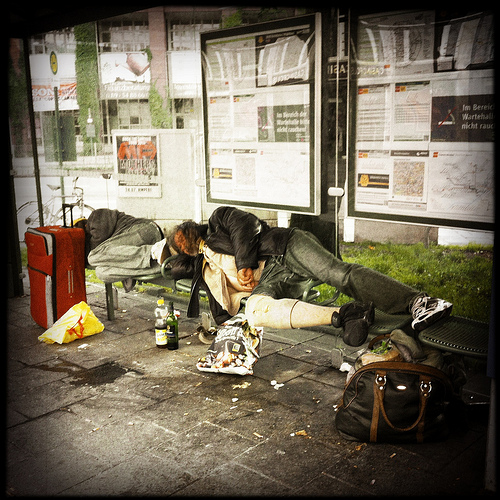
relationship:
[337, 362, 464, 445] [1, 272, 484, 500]
bag on sidewalk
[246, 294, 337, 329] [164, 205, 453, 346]
prostetic on vagabond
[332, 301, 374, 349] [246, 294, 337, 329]
shoe on prostetic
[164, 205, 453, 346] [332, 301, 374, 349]
vagabond wearing a shoe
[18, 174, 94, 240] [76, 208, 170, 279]
bike behind hobo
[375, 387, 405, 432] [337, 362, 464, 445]
handle on bag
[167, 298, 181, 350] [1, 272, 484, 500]
bottle on sidewalk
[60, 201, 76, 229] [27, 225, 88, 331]
handle of bag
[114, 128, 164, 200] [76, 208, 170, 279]
sign behind hobo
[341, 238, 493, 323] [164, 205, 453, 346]
bush behind vagabond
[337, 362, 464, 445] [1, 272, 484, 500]
bag on ground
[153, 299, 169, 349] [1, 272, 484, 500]
bottle on sidewalk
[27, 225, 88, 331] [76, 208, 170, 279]
bag near hobo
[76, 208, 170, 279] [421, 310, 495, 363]
hobo on bench